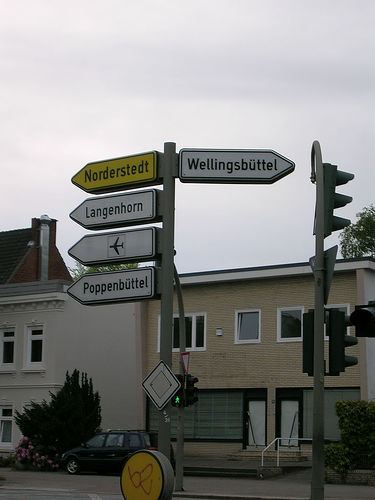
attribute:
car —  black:
[56, 427, 176, 476]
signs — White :
[59, 143, 286, 301]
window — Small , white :
[173, 313, 197, 351]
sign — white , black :
[63, 227, 159, 263]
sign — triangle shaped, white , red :
[185, 148, 281, 174]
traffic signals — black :
[299, 302, 374, 380]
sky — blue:
[2, 1, 374, 280]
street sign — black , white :
[77, 197, 165, 226]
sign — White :
[79, 192, 157, 234]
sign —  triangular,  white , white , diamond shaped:
[141, 360, 182, 413]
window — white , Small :
[321, 305, 349, 339]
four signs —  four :
[63, 146, 170, 311]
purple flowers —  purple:
[7, 429, 68, 476]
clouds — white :
[2, 2, 373, 275]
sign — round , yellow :
[118, 451, 167, 498]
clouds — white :
[96, 104, 276, 134]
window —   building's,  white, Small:
[237, 311, 258, 340]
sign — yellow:
[62, 150, 166, 195]